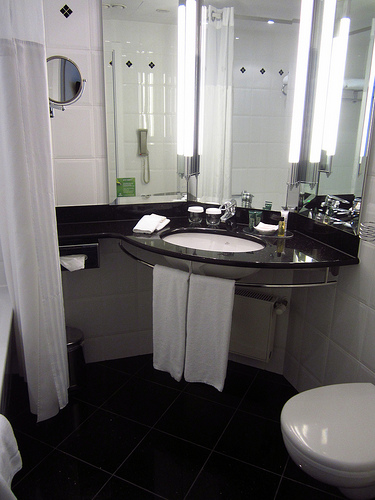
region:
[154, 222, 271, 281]
the bathroom sink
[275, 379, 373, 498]
the white toilet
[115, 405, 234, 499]
the dark bathroom floor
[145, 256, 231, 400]
the white towels under the sink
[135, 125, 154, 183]
the reflection of the phone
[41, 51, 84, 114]
the circular mirror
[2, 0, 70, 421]
the white shower curtain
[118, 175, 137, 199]
the green sticker in the mirror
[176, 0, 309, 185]
the lights in the mirror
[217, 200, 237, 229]
the water fixture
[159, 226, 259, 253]
this is a sink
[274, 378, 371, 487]
this is a toilet bowl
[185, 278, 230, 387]
this is a towel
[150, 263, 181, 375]
this is a towel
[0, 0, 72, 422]
this is a shower curtain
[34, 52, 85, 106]
a small round wall mirror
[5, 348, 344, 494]
the floor is black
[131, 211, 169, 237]
small hand towels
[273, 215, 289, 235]
a small bottle of oil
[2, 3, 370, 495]
this is a bathroom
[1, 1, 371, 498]
a black and white restroom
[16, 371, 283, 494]
the floor is covered in large black tiles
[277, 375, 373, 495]
a white toilet with the seat down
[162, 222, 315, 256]
white sink set in a black counter-top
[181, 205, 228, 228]
cups with white covers on them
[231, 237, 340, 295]
metal bar beneath counter-top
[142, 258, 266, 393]
white towels hung over metal bar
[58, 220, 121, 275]
facial tissue dispenser beneath counter-top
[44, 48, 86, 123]
round mirror affixed to wall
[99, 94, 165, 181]
telephone on wall reflected in mirror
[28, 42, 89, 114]
a small round mirror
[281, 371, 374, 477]
a white toilet lid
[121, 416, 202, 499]
a black floor tile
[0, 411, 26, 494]
the edge of a towel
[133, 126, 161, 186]
this is a phone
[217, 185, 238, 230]
this is a faucet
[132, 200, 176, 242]
this is a wash cloth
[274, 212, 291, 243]
a small yellow vial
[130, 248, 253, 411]
two large white towels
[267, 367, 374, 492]
this is a toilet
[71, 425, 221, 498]
The floor is made of tile.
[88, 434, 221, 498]
The floor is black.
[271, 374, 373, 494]
The toilet is white.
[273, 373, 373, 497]
The toilet seat is down.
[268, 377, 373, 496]
The toilet lid is down.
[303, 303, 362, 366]
The wall is made of tile.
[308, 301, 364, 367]
The tile is white.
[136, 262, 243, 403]
Two towels are hanging.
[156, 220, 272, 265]
The sink is white.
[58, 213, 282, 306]
The countertop is black.